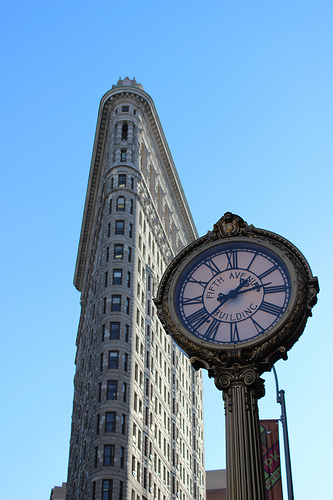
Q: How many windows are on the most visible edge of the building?
A: 15.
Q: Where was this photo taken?
A: Outside, during the day time.